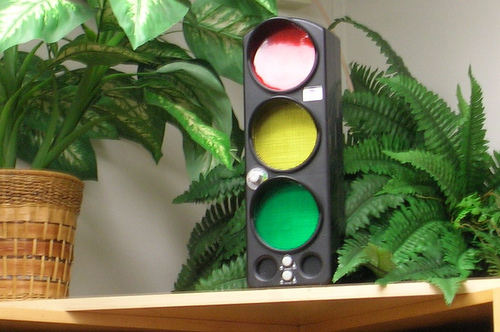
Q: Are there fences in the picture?
A: No, there are no fences.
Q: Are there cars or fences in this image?
A: No, there are no fences or cars.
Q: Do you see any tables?
A: Yes, there is a table.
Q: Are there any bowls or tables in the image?
A: Yes, there is a table.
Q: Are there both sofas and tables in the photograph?
A: No, there is a table but no sofas.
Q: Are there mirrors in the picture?
A: No, there are no mirrors.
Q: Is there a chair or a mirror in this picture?
A: No, there are no mirrors or chairs.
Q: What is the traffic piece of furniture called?
A: The piece of furniture is a table.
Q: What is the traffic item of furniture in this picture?
A: The piece of furniture is a table.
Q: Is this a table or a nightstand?
A: This is a table.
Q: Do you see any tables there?
A: Yes, there is a table.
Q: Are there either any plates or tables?
A: Yes, there is a table.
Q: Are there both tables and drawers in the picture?
A: No, there is a table but no drawers.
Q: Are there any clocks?
A: No, there are no clocks.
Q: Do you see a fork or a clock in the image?
A: No, there are no clocks or forks.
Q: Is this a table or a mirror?
A: This is a table.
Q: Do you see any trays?
A: No, there are no trays.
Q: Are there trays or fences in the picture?
A: No, there are no trays or fences.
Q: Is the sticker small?
A: Yes, the sticker is small.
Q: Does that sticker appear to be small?
A: Yes, the sticker is small.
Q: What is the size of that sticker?
A: The sticker is small.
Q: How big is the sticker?
A: The sticker is small.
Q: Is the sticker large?
A: No, the sticker is small.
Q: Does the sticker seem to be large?
A: No, the sticker is small.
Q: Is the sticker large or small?
A: The sticker is small.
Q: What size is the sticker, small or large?
A: The sticker is small.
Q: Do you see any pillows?
A: No, there are no pillows.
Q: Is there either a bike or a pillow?
A: No, there are no pillows or bikes.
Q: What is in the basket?
A: The leaves are in the basket.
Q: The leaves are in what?
A: The leaves are in the basket.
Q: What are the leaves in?
A: The leaves are in the basket.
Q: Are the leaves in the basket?
A: Yes, the leaves are in the basket.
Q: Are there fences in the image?
A: No, there are no fences.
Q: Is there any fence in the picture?
A: No, there are no fences.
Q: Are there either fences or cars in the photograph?
A: No, there are no fences or cars.